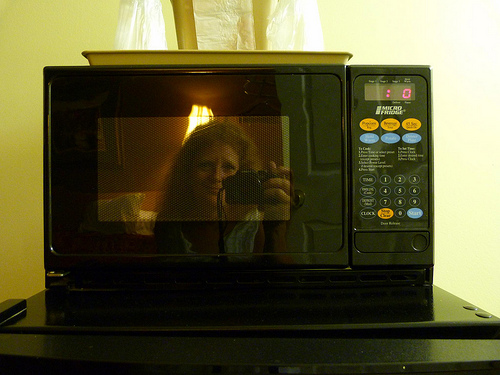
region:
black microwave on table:
[15, 55, 420, 309]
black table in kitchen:
[0, 290, 497, 374]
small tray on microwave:
[67, 23, 352, 65]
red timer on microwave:
[368, 84, 425, 108]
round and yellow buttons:
[358, 94, 415, 131]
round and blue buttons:
[358, 131, 415, 145]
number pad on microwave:
[374, 148, 424, 225]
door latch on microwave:
[348, 223, 425, 270]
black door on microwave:
[51, 60, 341, 297]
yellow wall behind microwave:
[348, 31, 496, 91]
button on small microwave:
[375, 204, 397, 226]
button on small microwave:
[403, 204, 427, 223]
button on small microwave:
[356, 111, 381, 131]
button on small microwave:
[376, 110, 405, 131]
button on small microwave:
[399, 115, 424, 129]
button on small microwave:
[353, 126, 376, 149]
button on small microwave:
[378, 129, 400, 145]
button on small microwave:
[401, 128, 421, 150]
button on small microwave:
[374, 173, 396, 185]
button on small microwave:
[406, 171, 421, 188]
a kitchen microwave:
[71, 44, 493, 215]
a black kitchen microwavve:
[58, 34, 493, 286]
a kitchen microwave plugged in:
[24, 36, 491, 358]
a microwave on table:
[25, 19, 461, 374]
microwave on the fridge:
[53, 27, 492, 324]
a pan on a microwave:
[32, 18, 329, 98]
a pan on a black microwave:
[72, 26, 418, 166]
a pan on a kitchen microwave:
[79, 12, 356, 160]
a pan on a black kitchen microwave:
[79, 33, 496, 194]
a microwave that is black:
[47, 45, 428, 312]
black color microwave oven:
[40, 65, 431, 292]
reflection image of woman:
[164, 122, 255, 257]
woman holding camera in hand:
[223, 163, 289, 255]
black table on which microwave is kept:
[4, 307, 488, 364]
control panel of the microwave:
[356, 116, 428, 234]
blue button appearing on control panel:
[356, 130, 428, 145]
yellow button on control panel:
[358, 115, 427, 130]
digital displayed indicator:
[363, 80, 414, 100]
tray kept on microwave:
[79, 47, 354, 64]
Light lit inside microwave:
[185, 101, 217, 115]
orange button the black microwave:
[358, 117, 379, 133]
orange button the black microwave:
[378, 116, 402, 131]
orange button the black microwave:
[401, 116, 421, 131]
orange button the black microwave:
[375, 205, 395, 221]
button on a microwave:
[360, 116, 378, 131]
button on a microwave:
[383, 118, 404, 131]